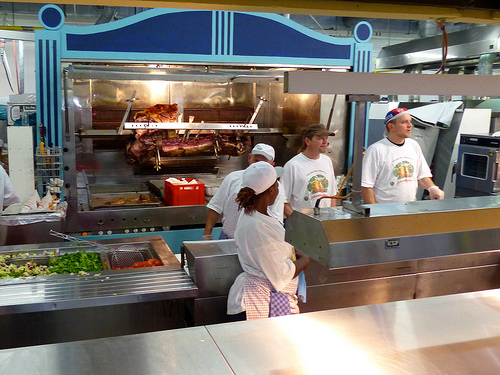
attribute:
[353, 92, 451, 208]
man — worker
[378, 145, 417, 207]
shirt — white, design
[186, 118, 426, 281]
people — cooking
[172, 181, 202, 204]
crate — red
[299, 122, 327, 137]
cap — white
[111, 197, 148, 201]
meat — large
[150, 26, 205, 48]
ceiling — blue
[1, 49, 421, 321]
kitchen — inside, metal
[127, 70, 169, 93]
lamp — large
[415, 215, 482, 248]
table — metal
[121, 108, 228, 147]
oven — background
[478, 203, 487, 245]
counter top — steel